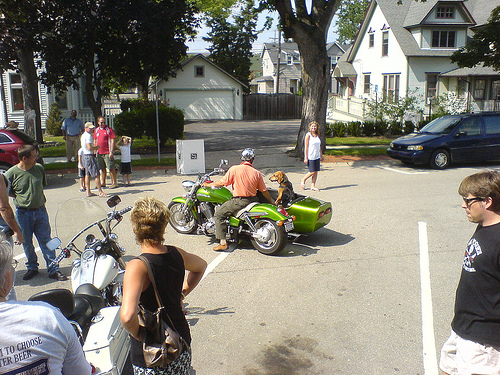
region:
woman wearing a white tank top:
[305, 133, 325, 161]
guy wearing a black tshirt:
[450, 223, 498, 350]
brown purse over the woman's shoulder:
[128, 253, 190, 371]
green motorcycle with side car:
[165, 158, 333, 256]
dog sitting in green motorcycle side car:
[268, 168, 297, 208]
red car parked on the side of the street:
[0, 121, 45, 176]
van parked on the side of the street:
[383, 106, 498, 170]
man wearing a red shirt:
[86, 123, 116, 155]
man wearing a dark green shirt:
[3, 163, 50, 210]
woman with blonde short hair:
[125, 195, 172, 248]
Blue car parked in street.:
[390, 97, 497, 187]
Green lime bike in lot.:
[166, 175, 291, 260]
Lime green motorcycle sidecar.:
[261, 177, 334, 227]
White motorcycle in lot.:
[35, 220, 145, 371]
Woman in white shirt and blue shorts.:
[295, 115, 326, 193]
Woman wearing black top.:
[115, 190, 201, 371]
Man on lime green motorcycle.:
[200, 147, 271, 249]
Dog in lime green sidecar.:
[261, 162, 297, 202]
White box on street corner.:
[170, 133, 210, 176]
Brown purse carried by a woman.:
[130, 255, 189, 369]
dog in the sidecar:
[263, 166, 320, 218]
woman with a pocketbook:
[115, 192, 207, 372]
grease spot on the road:
[236, 324, 331, 372]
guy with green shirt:
[9, 140, 62, 285]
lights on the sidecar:
[316, 207, 333, 230]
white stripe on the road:
[410, 201, 444, 373]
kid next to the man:
[92, 116, 139, 191]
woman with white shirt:
[297, 109, 327, 199]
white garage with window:
[163, 54, 248, 128]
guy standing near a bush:
[45, 101, 81, 162]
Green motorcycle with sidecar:
[162, 161, 362, 250]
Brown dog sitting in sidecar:
[268, 161, 340, 228]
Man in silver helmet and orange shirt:
[212, 141, 268, 203]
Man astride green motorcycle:
[183, 146, 279, 249]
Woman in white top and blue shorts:
[298, 120, 333, 190]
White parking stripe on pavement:
[414, 206, 442, 365]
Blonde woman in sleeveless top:
[118, 199, 199, 348]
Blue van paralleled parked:
[379, 108, 496, 177]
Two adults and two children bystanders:
[61, 109, 154, 198]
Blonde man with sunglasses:
[456, 157, 496, 229]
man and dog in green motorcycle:
[166, 145, 335, 255]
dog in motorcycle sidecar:
[266, 169, 334, 234]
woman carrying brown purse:
[118, 193, 207, 373]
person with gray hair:
[0, 228, 94, 374]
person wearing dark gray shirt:
[433, 164, 499, 373]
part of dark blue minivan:
[383, 108, 499, 170]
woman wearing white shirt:
[296, 117, 325, 192]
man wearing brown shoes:
[3, 143, 69, 283]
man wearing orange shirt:
[201, 144, 276, 250]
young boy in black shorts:
[118, 136, 138, 186]